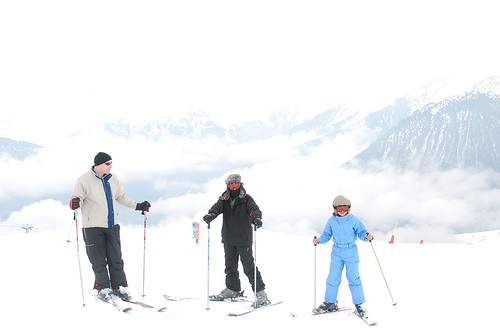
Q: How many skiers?
A: Three.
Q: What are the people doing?
A: Skiing.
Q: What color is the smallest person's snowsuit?
A: Blue.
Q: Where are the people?
A: Mountaintop.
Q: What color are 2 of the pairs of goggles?
A: Orange.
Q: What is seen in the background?
A: More mountains.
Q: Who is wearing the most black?
A: The person in the middle.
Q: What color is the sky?
A: White.